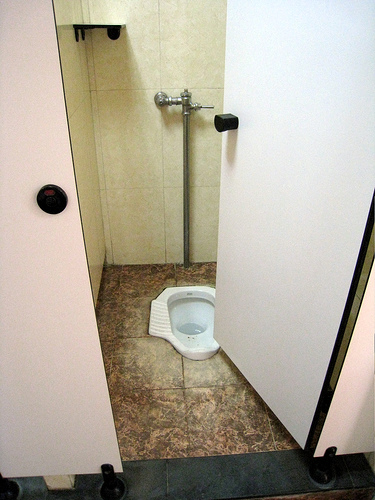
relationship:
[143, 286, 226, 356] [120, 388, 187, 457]
toilet in tile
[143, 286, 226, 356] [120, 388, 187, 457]
toilet within tile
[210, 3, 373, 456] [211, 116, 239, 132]
door has handle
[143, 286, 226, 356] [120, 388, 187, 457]
toilet on tile